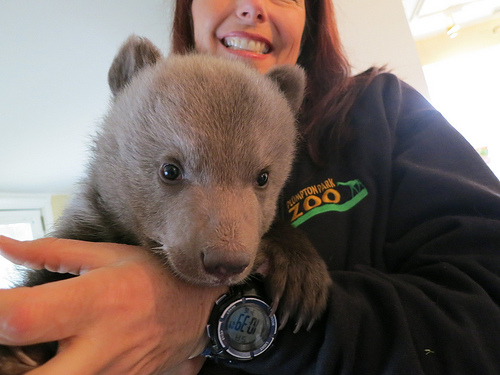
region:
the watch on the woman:
[200, 272, 278, 365]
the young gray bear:
[0, 33, 333, 338]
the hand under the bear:
[1, 236, 228, 373]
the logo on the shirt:
[285, 177, 367, 225]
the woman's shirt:
[257, 71, 498, 372]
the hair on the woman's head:
[170, 0, 393, 170]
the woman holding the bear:
[0, 0, 498, 374]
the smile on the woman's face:
[215, 30, 276, 57]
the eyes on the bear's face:
[160, 160, 270, 187]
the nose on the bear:
[203, 248, 250, 279]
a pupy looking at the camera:
[106, 94, 343, 264]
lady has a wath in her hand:
[159, 292, 452, 369]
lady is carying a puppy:
[63, 67, 308, 337]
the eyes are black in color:
[123, 161, 317, 220]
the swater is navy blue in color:
[366, 125, 468, 357]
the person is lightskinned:
[135, 313, 175, 374]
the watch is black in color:
[219, 275, 284, 374]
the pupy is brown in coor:
[123, 123, 279, 325]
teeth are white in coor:
[186, 5, 310, 75]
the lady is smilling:
[171, 27, 452, 266]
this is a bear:
[80, 53, 306, 260]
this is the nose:
[198, 252, 249, 278]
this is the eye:
[154, 160, 180, 186]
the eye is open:
[153, 158, 183, 185]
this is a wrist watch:
[210, 285, 275, 362]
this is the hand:
[116, 305, 188, 358]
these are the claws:
[271, 305, 317, 337]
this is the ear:
[268, 59, 305, 91]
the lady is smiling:
[220, 25, 273, 53]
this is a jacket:
[353, 96, 443, 211]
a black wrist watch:
[202, 268, 279, 366]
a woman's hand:
[0, 232, 230, 373]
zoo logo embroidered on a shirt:
[283, 176, 368, 227]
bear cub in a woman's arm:
[0, 35, 330, 373]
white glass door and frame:
[0, 191, 53, 289]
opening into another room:
[400, 4, 499, 179]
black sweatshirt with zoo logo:
[201, 68, 496, 373]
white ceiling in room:
[0, 0, 174, 192]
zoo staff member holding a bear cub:
[1, 0, 497, 374]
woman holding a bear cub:
[3, 0, 498, 374]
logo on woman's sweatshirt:
[285, 176, 370, 229]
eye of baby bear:
[158, 163, 183, 183]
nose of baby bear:
[197, 243, 247, 278]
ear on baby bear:
[107, 35, 157, 99]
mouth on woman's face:
[216, 29, 272, 59]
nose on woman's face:
[235, 1, 265, 23]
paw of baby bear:
[267, 221, 333, 336]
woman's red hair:
[171, 1, 393, 128]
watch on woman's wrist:
[202, 277, 279, 372]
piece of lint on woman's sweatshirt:
[422, 348, 435, 358]